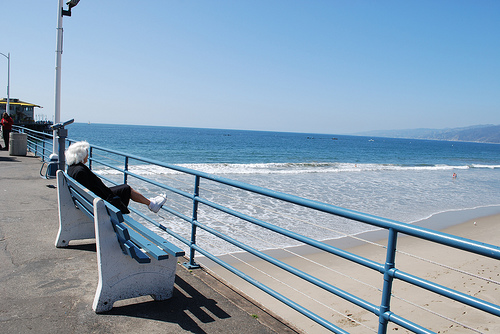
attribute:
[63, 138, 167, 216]
woman — watching, sitting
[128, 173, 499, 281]
beach — sandy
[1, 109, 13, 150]
person — standing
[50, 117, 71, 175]
telescope — here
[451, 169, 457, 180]
someone — swimming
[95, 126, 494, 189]
ocean — blue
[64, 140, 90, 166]
hair — white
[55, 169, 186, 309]
bench — blue, white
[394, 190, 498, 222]
water — shallow